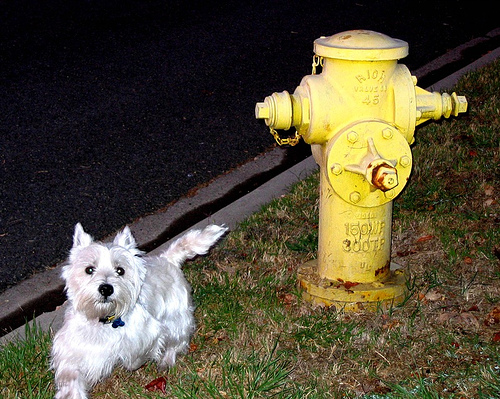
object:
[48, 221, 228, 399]
dog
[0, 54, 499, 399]
grass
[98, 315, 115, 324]
collar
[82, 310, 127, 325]
neck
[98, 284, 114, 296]
nose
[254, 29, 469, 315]
fire hydrant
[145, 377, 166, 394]
leaf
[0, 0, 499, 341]
road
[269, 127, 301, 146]
chain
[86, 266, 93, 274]
eye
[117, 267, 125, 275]
eye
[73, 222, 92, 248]
ear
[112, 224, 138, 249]
ear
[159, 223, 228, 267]
tail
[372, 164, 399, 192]
nut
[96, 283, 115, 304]
muzzle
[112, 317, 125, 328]
name tag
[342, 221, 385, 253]
lettering